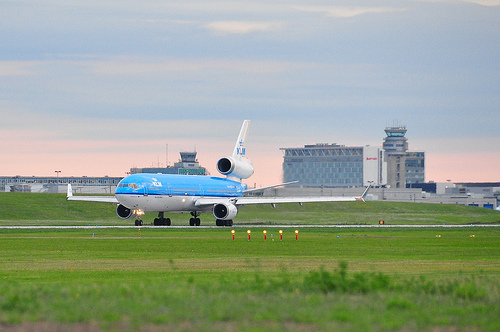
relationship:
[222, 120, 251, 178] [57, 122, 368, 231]
tail on plane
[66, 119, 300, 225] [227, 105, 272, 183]
plane has tail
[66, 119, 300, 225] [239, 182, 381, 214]
plane has wing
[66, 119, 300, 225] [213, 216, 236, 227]
plane has wheel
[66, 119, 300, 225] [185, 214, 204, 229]
plane has wheel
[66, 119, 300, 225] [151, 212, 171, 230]
plane has wheel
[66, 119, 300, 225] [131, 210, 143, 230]
plane has wheel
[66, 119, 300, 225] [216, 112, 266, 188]
plane has tail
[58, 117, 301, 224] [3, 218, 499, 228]
plane on runway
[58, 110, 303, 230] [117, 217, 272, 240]
airplane on ground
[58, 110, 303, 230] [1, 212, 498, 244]
airplane on large runway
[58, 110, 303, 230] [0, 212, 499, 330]
airplane on ground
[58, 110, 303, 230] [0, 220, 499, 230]
airplane on runway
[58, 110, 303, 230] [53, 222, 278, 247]
airplane on road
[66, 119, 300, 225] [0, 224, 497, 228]
plane on large runway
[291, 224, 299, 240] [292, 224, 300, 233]
post with light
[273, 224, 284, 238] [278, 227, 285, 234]
post with light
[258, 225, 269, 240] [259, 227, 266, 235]
post with light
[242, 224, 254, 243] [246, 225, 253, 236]
post with light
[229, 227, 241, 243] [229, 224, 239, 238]
post with light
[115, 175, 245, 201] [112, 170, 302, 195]
top half of plane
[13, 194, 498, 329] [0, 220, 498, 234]
grass next to runway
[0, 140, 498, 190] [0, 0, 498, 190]
lower section of sky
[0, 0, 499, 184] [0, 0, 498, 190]
cloud in sky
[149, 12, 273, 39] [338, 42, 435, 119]
cloud in sky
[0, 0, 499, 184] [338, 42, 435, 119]
cloud in sky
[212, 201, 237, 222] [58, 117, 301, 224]
engine on side of plane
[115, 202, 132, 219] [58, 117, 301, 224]
engine on side of plane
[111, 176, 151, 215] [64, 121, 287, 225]
front of plane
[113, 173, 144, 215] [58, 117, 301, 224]
nose of plane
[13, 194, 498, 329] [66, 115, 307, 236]
grass next to plane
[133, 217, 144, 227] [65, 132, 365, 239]
front tire of plane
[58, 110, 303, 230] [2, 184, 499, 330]
airplane on ground